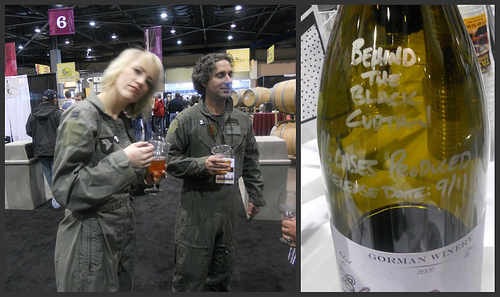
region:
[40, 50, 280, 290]
two people drinking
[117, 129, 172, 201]
the woman is holding a glass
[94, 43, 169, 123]
her hair is blonde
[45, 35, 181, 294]
the woman's head is turned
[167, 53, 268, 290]
the man is looking sideways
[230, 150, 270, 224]
he is holding a clipboard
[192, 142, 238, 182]
he is holding a glass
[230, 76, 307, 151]
barrels behind the people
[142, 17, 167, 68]
a banner hanging from the ceiling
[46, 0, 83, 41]
the number 6 on a banner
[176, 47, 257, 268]
this is a man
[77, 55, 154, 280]
this is a lady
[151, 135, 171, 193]
this is a glass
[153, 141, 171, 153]
the glass is shinny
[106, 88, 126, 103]
the lady is light skinned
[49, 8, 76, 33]
this is a post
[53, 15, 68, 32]
the writing is in white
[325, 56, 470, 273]
this is a bottle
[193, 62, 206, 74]
this is the hair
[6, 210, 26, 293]
this is the floor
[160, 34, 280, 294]
This is a person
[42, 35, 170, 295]
This is a person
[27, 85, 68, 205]
This is a person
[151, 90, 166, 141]
This is a person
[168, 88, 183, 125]
This is a person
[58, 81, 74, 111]
This is a person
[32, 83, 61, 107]
Head of a person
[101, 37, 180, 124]
Head of a person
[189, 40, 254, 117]
Head of a person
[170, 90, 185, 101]
Head of a person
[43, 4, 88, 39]
number six in white on purple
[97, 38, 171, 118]
head of a blond haired girl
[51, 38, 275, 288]
two people dressed in olive green jumpsuits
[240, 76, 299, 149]
display of three wood barrels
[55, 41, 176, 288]
woman holding a drink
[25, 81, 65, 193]
person in dark jacket with hood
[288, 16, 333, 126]
black polka dots on white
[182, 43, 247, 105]
head of man with dark curly hair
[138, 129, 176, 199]
amber colored liquid in a glass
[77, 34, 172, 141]
woman with head tilted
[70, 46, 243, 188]
Two people in flight suits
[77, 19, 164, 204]
Blonde haired girl in a flight suit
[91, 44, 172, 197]
Blonde haired girl holding a glass of wine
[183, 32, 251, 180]
Man with brown hair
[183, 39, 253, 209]
man with brown hair in flight suit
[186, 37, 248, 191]
Man holding an empty glass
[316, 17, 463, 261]
A bottle of wine that has been signed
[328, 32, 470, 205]
Wine bottle with silver writing on bottle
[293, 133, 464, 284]
Bottle of wine is almost empty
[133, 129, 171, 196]
Glass of wine